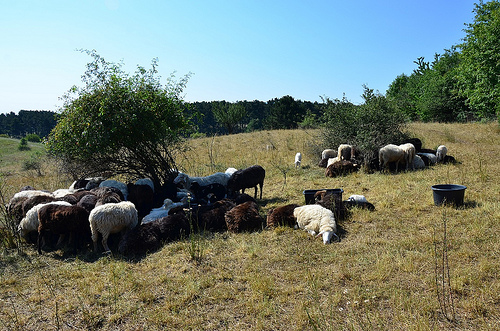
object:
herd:
[6, 138, 455, 261]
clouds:
[1, 0, 499, 115]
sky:
[0, 0, 497, 117]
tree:
[41, 50, 195, 183]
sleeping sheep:
[125, 191, 375, 262]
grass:
[1, 117, 497, 327]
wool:
[89, 201, 138, 240]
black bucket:
[431, 184, 467, 207]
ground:
[285, 162, 394, 251]